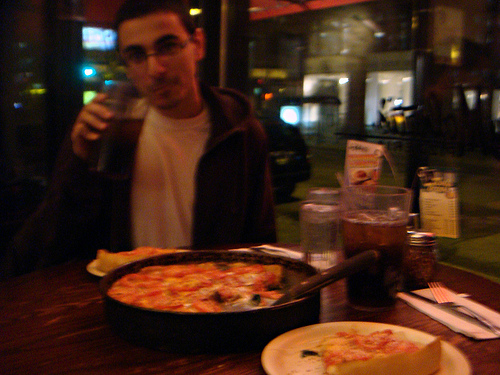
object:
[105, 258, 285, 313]
pizza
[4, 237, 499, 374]
table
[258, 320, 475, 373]
plate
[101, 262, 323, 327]
dish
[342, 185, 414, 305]
drink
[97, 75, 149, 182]
drink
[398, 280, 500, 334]
fork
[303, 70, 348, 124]
window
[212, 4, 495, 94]
background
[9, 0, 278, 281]
guy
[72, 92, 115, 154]
hand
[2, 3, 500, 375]
picture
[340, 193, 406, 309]
pop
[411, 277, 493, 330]
silverwear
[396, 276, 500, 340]
napkin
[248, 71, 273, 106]
lights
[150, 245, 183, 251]
edge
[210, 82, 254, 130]
hood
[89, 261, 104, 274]
edge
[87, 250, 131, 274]
plate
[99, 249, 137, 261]
edge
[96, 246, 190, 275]
food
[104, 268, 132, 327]
edge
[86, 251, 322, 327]
sufuria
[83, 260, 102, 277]
part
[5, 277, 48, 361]
part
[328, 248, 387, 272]
part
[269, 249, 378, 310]
handle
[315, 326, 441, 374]
food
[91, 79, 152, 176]
glass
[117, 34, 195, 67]
eye glass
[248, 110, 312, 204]
car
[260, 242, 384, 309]
pizza cutter